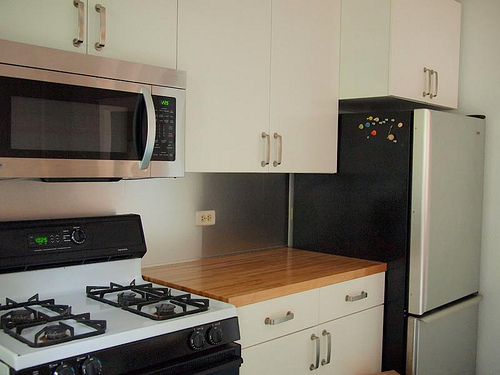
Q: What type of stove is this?
A: Gas.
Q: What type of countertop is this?
A: Butcher block.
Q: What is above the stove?
A: A microwave.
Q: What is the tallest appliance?
A: The refrigerator.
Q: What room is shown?
A: Kitchen.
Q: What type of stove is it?
A: Gas.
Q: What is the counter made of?
A: Wood.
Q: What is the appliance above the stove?
A: Microwave.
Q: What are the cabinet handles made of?
A: Metal.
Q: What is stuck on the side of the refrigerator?
A: Magnets.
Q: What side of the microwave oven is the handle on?
A: Right.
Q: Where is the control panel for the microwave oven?
A: On the right of the microwave.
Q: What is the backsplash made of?
A: Stainless steel.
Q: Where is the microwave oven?
A: Over the stove.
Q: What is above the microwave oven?
A: Cabinets.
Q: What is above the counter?
A: Cabinets.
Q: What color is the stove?
A: Black.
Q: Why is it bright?
A: Lights are on.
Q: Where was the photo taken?
A: The kitchen.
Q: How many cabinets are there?
A: Eight.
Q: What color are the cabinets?
A: White.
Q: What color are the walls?
A: Gray.